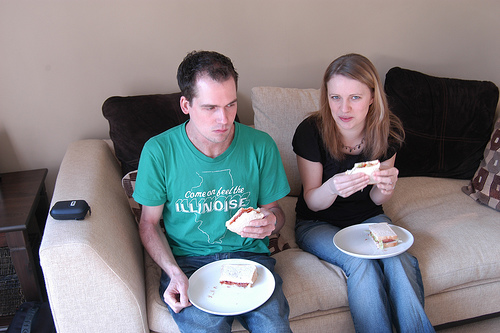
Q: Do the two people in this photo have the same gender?
A: No, they are both male and female.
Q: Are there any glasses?
A: No, there are no glasses.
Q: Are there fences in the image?
A: No, there are no fences.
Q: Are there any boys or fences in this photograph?
A: No, there are no fences or boys.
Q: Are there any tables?
A: Yes, there is a table.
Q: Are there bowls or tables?
A: Yes, there is a table.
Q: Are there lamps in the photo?
A: No, there are no lamps.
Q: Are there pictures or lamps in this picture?
A: No, there are no lamps or pictures.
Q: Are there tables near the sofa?
A: Yes, there is a table near the sofa.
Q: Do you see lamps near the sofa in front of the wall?
A: No, there is a table near the sofa.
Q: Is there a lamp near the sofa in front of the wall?
A: No, there is a table near the sofa.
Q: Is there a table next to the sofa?
A: Yes, there is a table next to the sofa.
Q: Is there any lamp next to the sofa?
A: No, there is a table next to the sofa.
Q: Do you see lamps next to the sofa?
A: No, there is a table next to the sofa.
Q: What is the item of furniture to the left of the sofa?
A: The piece of furniture is a table.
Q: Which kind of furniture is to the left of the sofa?
A: The piece of furniture is a table.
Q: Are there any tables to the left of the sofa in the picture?
A: Yes, there is a table to the left of the sofa.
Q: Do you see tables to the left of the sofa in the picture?
A: Yes, there is a table to the left of the sofa.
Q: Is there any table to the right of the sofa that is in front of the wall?
A: No, the table is to the left of the sofa.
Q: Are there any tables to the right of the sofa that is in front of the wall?
A: No, the table is to the left of the sofa.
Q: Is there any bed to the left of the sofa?
A: No, there is a table to the left of the sofa.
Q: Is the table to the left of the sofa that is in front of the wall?
A: Yes, the table is to the left of the sofa.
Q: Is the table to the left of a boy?
A: No, the table is to the left of the sofa.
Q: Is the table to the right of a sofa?
A: No, the table is to the left of a sofa.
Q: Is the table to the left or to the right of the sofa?
A: The table is to the left of the sofa.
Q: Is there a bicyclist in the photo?
A: No, there are no cyclists.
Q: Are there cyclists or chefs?
A: No, there are no cyclists or chefs.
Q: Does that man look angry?
A: Yes, the man is angry.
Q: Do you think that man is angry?
A: Yes, the man is angry.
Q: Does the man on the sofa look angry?
A: Yes, the man is angry.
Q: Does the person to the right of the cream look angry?
A: Yes, the man is angry.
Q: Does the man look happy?
A: No, the man is angry.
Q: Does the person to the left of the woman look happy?
A: No, the man is angry.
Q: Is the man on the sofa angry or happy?
A: The man is angry.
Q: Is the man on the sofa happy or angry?
A: The man is angry.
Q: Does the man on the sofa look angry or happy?
A: The man is angry.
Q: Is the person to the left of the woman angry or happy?
A: The man is angry.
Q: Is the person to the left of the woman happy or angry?
A: The man is angry.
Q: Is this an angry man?
A: Yes, this is an angry man.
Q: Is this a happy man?
A: No, this is an angry man.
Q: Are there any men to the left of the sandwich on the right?
A: Yes, there is a man to the left of the sandwich.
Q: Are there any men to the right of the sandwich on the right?
A: No, the man is to the left of the sandwich.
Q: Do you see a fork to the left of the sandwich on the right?
A: No, there is a man to the left of the sandwich.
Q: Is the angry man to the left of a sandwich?
A: Yes, the man is to the left of a sandwich.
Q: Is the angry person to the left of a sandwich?
A: Yes, the man is to the left of a sandwich.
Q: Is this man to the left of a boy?
A: No, the man is to the left of a sandwich.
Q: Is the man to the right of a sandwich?
A: No, the man is to the left of a sandwich.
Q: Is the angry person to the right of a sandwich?
A: No, the man is to the left of a sandwich.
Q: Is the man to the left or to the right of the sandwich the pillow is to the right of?
A: The man is to the left of the sandwich.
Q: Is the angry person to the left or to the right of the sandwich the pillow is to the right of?
A: The man is to the left of the sandwich.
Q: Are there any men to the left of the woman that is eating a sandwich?
A: Yes, there is a man to the left of the woman.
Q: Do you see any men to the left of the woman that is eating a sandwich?
A: Yes, there is a man to the left of the woman.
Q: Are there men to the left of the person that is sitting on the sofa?
A: Yes, there is a man to the left of the woman.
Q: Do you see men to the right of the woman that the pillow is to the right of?
A: No, the man is to the left of the woman.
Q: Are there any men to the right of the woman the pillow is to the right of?
A: No, the man is to the left of the woman.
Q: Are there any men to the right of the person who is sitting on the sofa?
A: No, the man is to the left of the woman.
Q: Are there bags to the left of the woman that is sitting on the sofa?
A: No, there is a man to the left of the woman.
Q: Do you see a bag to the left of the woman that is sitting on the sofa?
A: No, there is a man to the left of the woman.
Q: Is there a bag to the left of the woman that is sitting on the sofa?
A: No, there is a man to the left of the woman.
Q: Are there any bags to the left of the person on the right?
A: No, there is a man to the left of the woman.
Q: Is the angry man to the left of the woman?
A: Yes, the man is to the left of the woman.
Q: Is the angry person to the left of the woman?
A: Yes, the man is to the left of the woman.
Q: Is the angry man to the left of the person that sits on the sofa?
A: Yes, the man is to the left of the woman.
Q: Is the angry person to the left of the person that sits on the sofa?
A: Yes, the man is to the left of the woman.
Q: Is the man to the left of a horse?
A: No, the man is to the left of the woman.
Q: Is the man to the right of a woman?
A: No, the man is to the left of a woman.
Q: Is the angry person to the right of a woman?
A: No, the man is to the left of a woman.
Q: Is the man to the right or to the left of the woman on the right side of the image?
A: The man is to the left of the woman.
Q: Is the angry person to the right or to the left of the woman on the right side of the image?
A: The man is to the left of the woman.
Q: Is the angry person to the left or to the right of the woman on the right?
A: The man is to the left of the woman.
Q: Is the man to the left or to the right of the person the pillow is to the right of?
A: The man is to the left of the woman.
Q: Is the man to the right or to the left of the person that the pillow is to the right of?
A: The man is to the left of the woman.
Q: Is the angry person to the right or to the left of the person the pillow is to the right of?
A: The man is to the left of the woman.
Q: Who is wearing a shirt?
A: The man is wearing a shirt.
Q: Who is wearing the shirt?
A: The man is wearing a shirt.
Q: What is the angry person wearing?
A: The man is wearing a shirt.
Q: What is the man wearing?
A: The man is wearing a shirt.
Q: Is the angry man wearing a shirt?
A: Yes, the man is wearing a shirt.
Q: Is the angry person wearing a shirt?
A: Yes, the man is wearing a shirt.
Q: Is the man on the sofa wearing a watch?
A: No, the man is wearing a shirt.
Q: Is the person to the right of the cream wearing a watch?
A: No, the man is wearing a shirt.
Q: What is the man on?
A: The man is on the sofa.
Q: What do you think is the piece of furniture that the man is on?
A: The piece of furniture is a sofa.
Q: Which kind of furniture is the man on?
A: The man is on the sofa.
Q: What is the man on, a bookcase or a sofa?
A: The man is on a sofa.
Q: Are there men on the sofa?
A: Yes, there is a man on the sofa.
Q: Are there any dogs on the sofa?
A: No, there is a man on the sofa.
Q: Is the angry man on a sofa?
A: Yes, the man is on a sofa.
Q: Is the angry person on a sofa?
A: Yes, the man is on a sofa.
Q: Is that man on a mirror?
A: No, the man is on a sofa.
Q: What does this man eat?
A: The man eats a sandwich.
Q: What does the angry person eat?
A: The man eats a sandwich.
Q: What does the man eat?
A: The man eats a sandwich.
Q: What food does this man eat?
A: The man eats a sandwich.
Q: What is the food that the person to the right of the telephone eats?
A: The food is a sandwich.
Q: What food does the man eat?
A: The man eats a sandwich.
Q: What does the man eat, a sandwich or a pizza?
A: The man eats a sandwich.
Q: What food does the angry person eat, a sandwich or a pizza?
A: The man eats a sandwich.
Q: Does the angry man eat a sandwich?
A: Yes, the man eats a sandwich.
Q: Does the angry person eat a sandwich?
A: Yes, the man eats a sandwich.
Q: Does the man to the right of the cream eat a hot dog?
A: No, the man eats a sandwich.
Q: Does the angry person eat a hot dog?
A: No, the man eats a sandwich.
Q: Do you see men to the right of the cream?
A: Yes, there is a man to the right of the cream.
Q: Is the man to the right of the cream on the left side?
A: Yes, the man is to the right of the cream.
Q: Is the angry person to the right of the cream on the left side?
A: Yes, the man is to the right of the cream.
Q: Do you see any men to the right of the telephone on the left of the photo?
A: Yes, there is a man to the right of the phone.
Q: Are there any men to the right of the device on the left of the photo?
A: Yes, there is a man to the right of the phone.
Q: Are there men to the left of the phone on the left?
A: No, the man is to the right of the phone.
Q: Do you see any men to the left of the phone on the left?
A: No, the man is to the right of the phone.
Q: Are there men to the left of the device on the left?
A: No, the man is to the right of the phone.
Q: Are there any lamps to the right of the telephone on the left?
A: No, there is a man to the right of the telephone.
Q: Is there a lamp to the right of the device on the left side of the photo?
A: No, there is a man to the right of the telephone.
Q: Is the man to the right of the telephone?
A: Yes, the man is to the right of the telephone.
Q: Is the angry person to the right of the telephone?
A: Yes, the man is to the right of the telephone.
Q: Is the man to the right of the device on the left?
A: Yes, the man is to the right of the telephone.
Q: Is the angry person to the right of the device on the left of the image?
A: Yes, the man is to the right of the telephone.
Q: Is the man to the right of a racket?
A: No, the man is to the right of the telephone.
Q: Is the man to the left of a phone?
A: No, the man is to the right of a phone.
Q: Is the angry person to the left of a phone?
A: No, the man is to the right of a phone.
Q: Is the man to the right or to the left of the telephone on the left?
A: The man is to the right of the phone.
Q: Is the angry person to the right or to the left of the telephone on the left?
A: The man is to the right of the phone.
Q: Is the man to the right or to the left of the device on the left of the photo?
A: The man is to the right of the phone.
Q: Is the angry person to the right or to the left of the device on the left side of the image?
A: The man is to the right of the phone.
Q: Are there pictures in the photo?
A: No, there are no pictures.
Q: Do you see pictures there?
A: No, there are no pictures.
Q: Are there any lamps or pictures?
A: No, there are no pictures or lamps.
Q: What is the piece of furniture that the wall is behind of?
A: The piece of furniture is a sofa.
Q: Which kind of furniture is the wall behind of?
A: The wall is behind the sofa.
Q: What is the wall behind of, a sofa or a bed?
A: The wall is behind a sofa.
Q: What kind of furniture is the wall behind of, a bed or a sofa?
A: The wall is behind a sofa.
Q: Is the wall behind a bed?
A: No, the wall is behind a sofa.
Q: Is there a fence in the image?
A: No, there are no fences.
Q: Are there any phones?
A: Yes, there is a phone.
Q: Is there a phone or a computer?
A: Yes, there is a phone.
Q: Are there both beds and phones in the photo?
A: No, there is a phone but no beds.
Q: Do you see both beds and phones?
A: No, there is a phone but no beds.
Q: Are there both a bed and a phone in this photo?
A: No, there is a phone but no beds.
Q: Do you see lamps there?
A: No, there are no lamps.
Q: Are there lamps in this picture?
A: No, there are no lamps.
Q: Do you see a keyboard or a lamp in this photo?
A: No, there are no lamps or keyboards.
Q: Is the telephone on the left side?
A: Yes, the telephone is on the left of the image.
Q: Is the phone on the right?
A: No, the phone is on the left of the image.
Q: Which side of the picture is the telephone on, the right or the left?
A: The telephone is on the left of the image.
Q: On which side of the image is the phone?
A: The phone is on the left of the image.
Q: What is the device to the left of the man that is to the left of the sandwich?
A: The device is a phone.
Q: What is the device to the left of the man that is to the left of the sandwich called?
A: The device is a phone.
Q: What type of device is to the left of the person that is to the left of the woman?
A: The device is a phone.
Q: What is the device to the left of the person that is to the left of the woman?
A: The device is a phone.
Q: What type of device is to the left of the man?
A: The device is a phone.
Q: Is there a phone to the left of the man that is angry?
A: Yes, there is a phone to the left of the man.